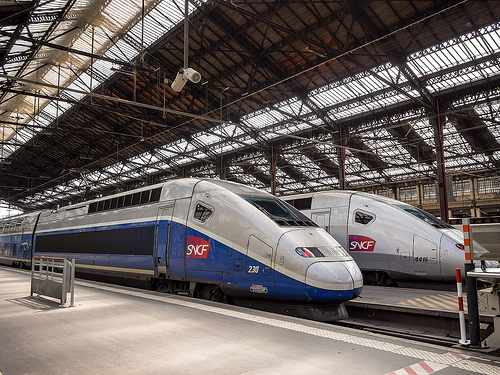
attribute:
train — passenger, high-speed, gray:
[1, 173, 367, 329]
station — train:
[1, 1, 499, 374]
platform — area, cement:
[2, 266, 499, 373]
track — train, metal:
[322, 298, 499, 361]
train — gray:
[277, 189, 497, 290]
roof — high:
[2, 1, 500, 215]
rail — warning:
[460, 213, 483, 352]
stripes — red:
[450, 270, 468, 314]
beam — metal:
[2, 69, 430, 169]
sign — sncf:
[182, 233, 213, 262]